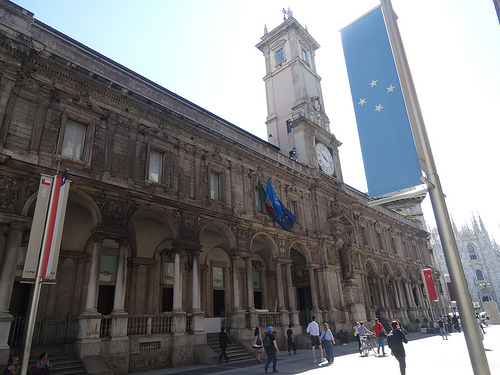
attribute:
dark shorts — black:
[309, 333, 320, 347]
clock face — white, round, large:
[313, 142, 337, 178]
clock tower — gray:
[250, 7, 348, 186]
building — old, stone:
[0, 0, 454, 373]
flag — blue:
[261, 178, 299, 234]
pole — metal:
[379, 0, 495, 373]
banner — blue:
[337, 4, 428, 205]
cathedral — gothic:
[424, 213, 499, 326]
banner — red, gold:
[419, 265, 441, 305]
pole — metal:
[13, 163, 64, 373]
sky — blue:
[15, 2, 499, 242]